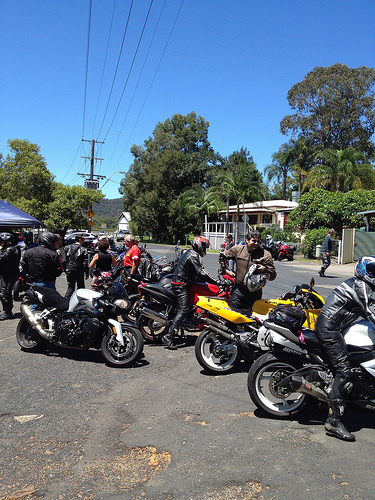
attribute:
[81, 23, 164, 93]
cables — suspended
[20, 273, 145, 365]
motorcycle — yellow, red, black, rode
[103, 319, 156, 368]
wheel — black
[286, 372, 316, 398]
pipe — metal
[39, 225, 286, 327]
bikers — gathering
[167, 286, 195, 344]
panst — leather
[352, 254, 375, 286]
helmet — blue, red, black, held, worn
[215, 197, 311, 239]
house — red, white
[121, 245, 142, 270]
shirt — red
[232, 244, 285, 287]
shirt — brown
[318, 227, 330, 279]
man — walking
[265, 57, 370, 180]
trees — green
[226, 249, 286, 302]
jacket — brown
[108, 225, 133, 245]
car — here